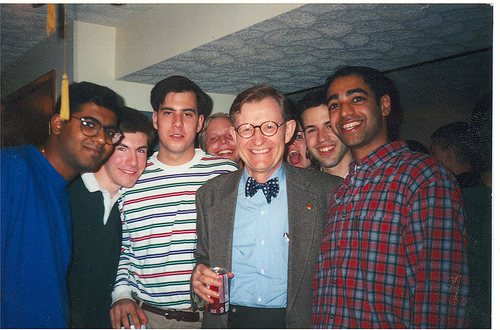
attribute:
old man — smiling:
[196, 86, 346, 327]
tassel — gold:
[60, 74, 70, 119]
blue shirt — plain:
[1, 145, 74, 329]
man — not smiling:
[111, 75, 240, 328]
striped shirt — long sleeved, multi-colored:
[113, 150, 240, 307]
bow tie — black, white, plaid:
[245, 176, 280, 201]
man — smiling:
[312, 65, 466, 326]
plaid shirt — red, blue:
[311, 138, 471, 329]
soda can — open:
[206, 265, 231, 314]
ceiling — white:
[3, 2, 494, 94]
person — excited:
[288, 118, 320, 169]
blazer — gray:
[285, 162, 346, 329]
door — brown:
[0, 69, 57, 150]